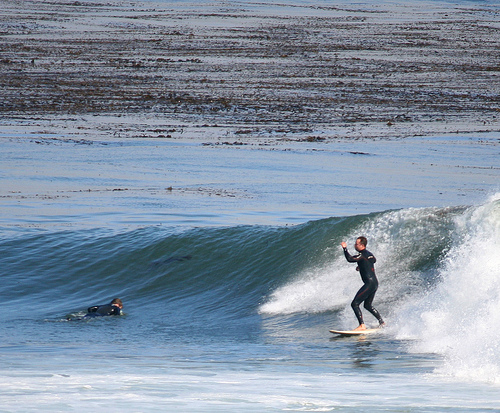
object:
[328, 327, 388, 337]
surfboard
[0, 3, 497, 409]
water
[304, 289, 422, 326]
board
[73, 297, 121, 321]
dog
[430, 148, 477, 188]
ground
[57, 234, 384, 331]
two people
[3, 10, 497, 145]
seaweed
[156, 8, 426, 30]
clouds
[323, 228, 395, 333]
man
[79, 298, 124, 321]
man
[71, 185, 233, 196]
weed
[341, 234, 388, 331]
man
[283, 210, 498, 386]
spray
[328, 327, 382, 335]
board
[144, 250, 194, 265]
seaweed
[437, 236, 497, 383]
foam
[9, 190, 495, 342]
wave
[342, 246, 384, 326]
suit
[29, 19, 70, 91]
clouds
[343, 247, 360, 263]
arms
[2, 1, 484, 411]
ocean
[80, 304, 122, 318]
wetsuit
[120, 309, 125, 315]
surfboard